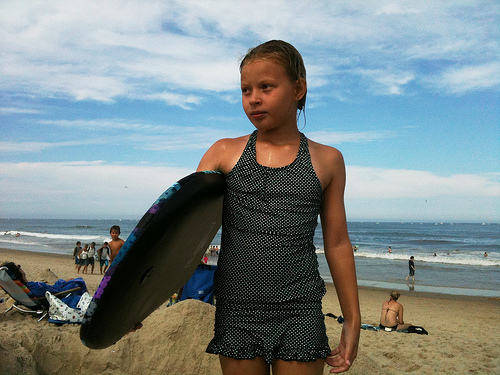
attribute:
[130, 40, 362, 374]
girl — standing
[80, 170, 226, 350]
boogie board — black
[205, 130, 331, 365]
bathing suit — black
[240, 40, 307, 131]
hair — wet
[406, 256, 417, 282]
person — standing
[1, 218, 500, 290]
water — dark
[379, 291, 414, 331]
person — sitting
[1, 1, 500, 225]
sky — blue